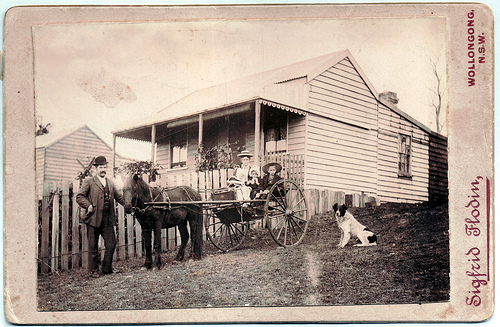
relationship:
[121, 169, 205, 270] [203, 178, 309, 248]
horse pulls carriage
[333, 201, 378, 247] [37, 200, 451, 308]
dog on grass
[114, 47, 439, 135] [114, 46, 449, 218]
roof of house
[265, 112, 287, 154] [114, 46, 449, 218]
window of house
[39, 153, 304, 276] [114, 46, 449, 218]
fence by house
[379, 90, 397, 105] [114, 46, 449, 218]
chimney of house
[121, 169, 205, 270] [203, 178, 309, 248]
horse and carriage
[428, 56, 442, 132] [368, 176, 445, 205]
tree in yard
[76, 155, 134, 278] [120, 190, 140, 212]
man holds reigns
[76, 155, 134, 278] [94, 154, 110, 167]
man has hat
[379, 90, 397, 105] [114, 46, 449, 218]
chimney on house